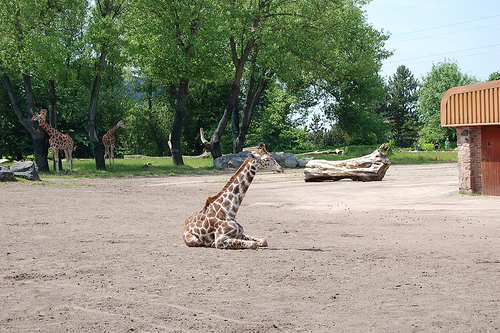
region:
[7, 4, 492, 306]
a park for giraffe to live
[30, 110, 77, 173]
giraffe next to tree in the background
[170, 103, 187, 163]
tree trunk in the grass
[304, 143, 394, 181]
large tree stump on the ground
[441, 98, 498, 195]
grounds keeper supply room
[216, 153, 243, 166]
large rocks in grass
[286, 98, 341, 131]
sky behind trees in park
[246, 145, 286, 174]
giraffe head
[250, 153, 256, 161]
giraffe ear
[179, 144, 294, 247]
giraffe kneeling down on ground in park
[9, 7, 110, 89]
The trees have lots of foilage.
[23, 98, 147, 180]
These giraffes are standing.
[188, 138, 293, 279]
This giraffe is resting.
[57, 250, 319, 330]
The ground is tan.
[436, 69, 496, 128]
The buliding's roof is orange.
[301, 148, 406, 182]
This is a log.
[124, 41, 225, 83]
The leaves are green.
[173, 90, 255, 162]
The tree trunks are brown.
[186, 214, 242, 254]
The giraffe is brown and white.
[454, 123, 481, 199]
This is made of brick.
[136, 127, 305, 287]
One animal in the shot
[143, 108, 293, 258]
Animal is brown, yellow, and white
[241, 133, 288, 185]
Looking to the right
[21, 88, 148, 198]
Animals in the back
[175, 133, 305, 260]
Its sitting down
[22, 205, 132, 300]
Sand on the ground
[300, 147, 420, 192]
Log on the ground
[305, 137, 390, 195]
Log is brown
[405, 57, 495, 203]
Building to the side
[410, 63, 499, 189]
Building is made of bricks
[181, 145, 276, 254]
A giraffe is laying down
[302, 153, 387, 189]
A log in the sand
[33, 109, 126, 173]
Two giraffes stand by trees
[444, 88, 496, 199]
The building has a ridged roof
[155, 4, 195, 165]
A single tree stands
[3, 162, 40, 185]
Two grey rocks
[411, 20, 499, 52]
Power lines in the sky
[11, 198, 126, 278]
The ground is sandy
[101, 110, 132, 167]
The giraffe looks to the right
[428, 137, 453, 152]
People looking in the background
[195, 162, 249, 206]
The giraffes mane is brown.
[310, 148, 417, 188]
The log is brown.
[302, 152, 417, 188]
This is a piece of wood.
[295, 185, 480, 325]
The ground is made of dirt.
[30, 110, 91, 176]
The giraffe is brown and white.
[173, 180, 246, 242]
The giraffe has a spotted pattern.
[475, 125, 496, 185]
The door is red.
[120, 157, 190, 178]
The grass is green.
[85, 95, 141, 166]
The girraffe is standing.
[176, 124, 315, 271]
This giraffe is sleeping.